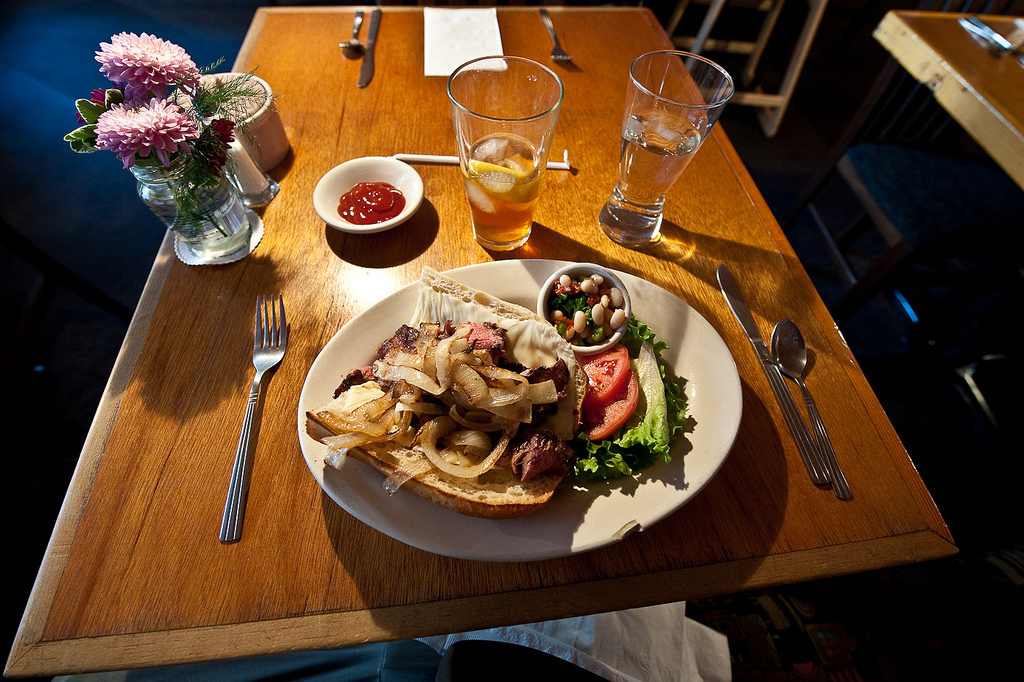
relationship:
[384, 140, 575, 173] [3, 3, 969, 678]
drinkingstraw on table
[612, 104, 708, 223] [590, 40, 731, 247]
ice water in glass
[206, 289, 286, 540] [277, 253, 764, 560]
fork beside plate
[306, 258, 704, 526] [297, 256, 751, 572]
food on plate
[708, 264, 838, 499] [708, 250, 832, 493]
knife beside plate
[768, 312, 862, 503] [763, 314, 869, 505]
spoon beside knife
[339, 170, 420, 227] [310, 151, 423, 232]
ketchup in bowl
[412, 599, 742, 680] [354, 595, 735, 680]
napkin on lap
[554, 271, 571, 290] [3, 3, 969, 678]
food on table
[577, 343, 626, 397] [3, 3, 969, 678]
food on table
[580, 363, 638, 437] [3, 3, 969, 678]
food on table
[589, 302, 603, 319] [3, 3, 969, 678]
food on table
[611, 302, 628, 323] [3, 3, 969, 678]
food on table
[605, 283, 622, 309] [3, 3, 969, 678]
food on table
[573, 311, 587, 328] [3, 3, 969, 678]
food on table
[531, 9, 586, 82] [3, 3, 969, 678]
fork on table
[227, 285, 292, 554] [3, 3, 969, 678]
fork on table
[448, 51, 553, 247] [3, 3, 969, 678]
glass on table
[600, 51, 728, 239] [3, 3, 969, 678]
glass on table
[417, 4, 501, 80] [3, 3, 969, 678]
napkin on table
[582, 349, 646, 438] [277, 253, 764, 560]
tomatoes on plate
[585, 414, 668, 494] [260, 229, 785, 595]
lettuce on plate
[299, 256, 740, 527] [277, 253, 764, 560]
food on plate